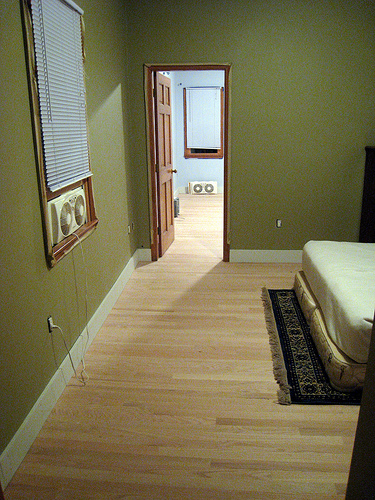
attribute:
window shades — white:
[32, 2, 110, 195]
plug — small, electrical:
[46, 316, 62, 335]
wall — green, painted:
[244, 47, 372, 134]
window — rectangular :
[179, 83, 227, 161]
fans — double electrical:
[166, 151, 234, 215]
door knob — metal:
[170, 167, 176, 174]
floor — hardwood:
[17, 196, 366, 498]